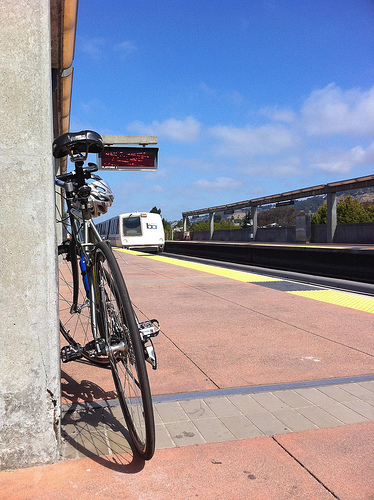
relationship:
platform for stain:
[123, 238, 372, 484] [93, 211, 166, 253]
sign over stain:
[110, 136, 163, 166] [93, 211, 166, 253]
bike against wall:
[45, 115, 197, 469] [5, 6, 57, 465]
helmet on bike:
[51, 172, 131, 231] [45, 115, 197, 469]